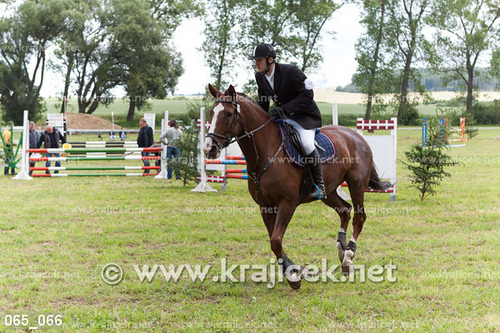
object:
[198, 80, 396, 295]
horse's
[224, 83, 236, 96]
ear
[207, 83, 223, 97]
ear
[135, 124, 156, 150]
jacket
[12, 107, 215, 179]
fence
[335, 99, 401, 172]
fence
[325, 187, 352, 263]
leg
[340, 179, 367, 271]
leg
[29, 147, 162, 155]
pole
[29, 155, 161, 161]
pole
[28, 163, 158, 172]
pole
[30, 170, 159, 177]
pole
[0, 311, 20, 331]
numbers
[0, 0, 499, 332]
photo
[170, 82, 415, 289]
horse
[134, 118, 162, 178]
man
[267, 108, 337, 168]
horse saddle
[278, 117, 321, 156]
pants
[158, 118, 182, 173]
person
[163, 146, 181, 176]
jeans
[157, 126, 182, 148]
sweatshirt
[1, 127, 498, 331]
grass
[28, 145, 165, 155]
poles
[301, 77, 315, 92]
patch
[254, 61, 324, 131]
jacket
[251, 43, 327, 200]
man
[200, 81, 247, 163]
head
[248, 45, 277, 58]
helmet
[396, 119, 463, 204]
tree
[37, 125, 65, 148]
coat